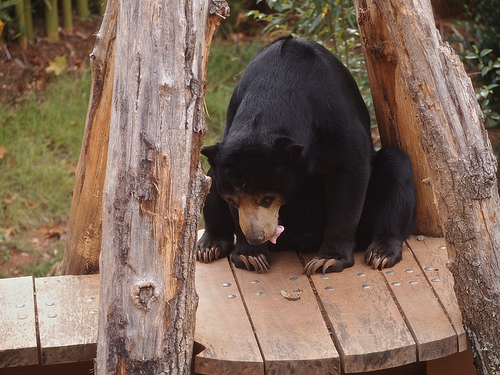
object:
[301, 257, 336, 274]
nails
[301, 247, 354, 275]
paw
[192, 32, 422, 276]
bear is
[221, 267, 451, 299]
screws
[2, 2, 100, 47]
bamboo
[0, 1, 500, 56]
background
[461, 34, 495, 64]
leave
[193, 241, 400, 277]
claws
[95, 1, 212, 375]
trunk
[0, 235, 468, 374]
bridge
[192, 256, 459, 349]
board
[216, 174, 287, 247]
face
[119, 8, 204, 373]
bark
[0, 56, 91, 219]
grass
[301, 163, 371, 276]
back leg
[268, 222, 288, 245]
thing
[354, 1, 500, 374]
trunk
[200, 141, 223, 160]
ears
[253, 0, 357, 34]
bush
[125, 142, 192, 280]
marks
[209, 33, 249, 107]
grass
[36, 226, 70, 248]
leaf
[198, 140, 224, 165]
ear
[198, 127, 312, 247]
head